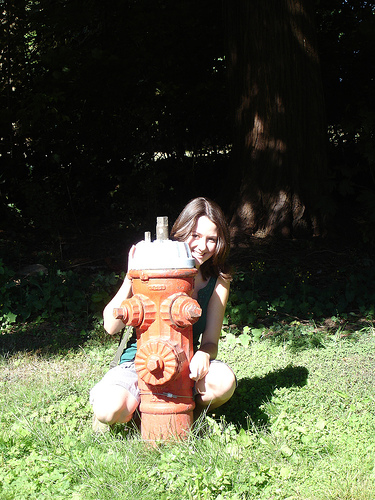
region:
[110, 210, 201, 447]
a fire hydrant surrounded by grass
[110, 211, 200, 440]
the fire hydrant is faded orange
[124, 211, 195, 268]
the cap on the top of the hydrant is white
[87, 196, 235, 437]
a girl is behind the hydrant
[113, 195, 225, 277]
the girl is peaking around the side of a hydrant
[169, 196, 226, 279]
the girl has brown hair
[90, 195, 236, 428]
the girl is wearing a green tank top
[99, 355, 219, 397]
blue jean shorts are on the girl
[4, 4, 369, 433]
woods are in the background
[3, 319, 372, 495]
weeds and grass are around the hydrant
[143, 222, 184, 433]
this is a hydrant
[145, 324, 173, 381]
the hydrant is red in color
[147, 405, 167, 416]
the hydrant is red in color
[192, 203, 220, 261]
this is a lady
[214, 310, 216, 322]
the lady is light skinned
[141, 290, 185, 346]
the hydrant is metallic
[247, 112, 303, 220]
this is a tree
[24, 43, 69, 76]
the tree has a green leaves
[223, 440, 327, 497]
this is ground is having grass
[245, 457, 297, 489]
the grass is green in color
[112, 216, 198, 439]
an orange fire hydrant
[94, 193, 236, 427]
woman posing behind fire hydrant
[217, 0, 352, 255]
tree behind woman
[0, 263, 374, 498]
grassy area under woman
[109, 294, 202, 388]
spouts on fire hydrant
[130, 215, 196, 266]
white top of fire hydrant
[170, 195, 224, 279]
woman's long, brown hair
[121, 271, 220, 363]
green tank top on woman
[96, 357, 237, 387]
light brown shorts on woman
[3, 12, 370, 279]
shady area behind woman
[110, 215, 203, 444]
Orange fire hydrant in front of girl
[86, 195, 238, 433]
Pretty girl squatting behind fire hydrant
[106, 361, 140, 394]
Part of purple shorts worn by girl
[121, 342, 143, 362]
Small part of blue shirt on girl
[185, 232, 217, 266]
Smile of a pretty girl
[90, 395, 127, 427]
Knee of girl by fire hydrant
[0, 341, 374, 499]
Green ground vegetation around girl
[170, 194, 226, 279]
Brown hair of pretty girl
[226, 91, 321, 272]
Bottom part of thick tree behind girl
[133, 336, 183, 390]
Large orange valve on fire hydrant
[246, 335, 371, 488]
A small section of grass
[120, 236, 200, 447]
A large orange fire extinguisher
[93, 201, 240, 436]
A lady holding a fire extinguisher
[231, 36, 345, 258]
Bottom of a tree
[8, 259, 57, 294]
A large rock in the grass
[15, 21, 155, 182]
A small section of a bush in the shade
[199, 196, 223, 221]
A patch of the lady's brunette hair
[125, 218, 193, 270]
Silver top of the fire extinguisher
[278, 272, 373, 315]
Small leaves in the shade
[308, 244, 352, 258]
A small stick